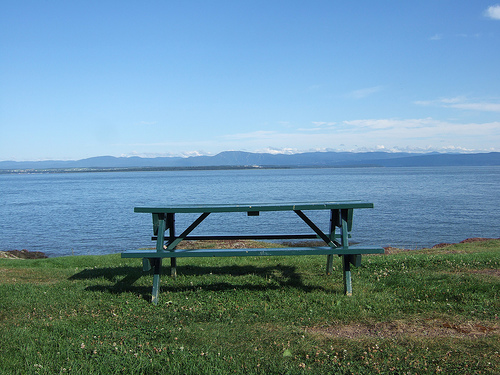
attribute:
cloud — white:
[319, 107, 498, 129]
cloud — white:
[230, 129, 497, 153]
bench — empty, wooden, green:
[121, 200, 389, 298]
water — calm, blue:
[14, 165, 493, 245]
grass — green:
[173, 300, 256, 358]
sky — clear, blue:
[2, 2, 495, 152]